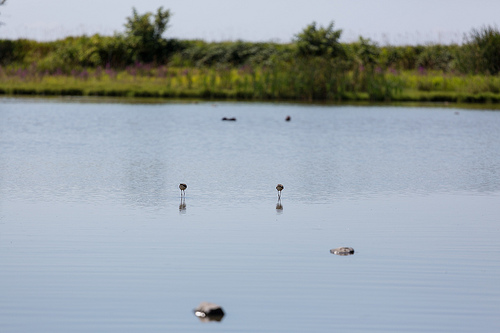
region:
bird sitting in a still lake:
[325, 242, 357, 263]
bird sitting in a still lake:
[273, 179, 286, 206]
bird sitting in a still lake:
[177, 177, 191, 204]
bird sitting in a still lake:
[283, 112, 293, 126]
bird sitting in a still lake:
[218, 112, 238, 123]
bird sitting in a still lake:
[186, 295, 226, 325]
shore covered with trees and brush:
[0, 0, 495, 99]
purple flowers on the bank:
[0, 54, 459, 86]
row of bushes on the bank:
[40, 11, 499, 71]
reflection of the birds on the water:
[174, 198, 285, 215]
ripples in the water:
[3, 97, 493, 205]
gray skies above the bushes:
[3, 3, 498, 41]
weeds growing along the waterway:
[161, 63, 402, 101]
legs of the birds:
[175, 188, 284, 195]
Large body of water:
[364, 121, 461, 202]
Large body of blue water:
[23, 117, 119, 214]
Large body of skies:
[228, 8, 280, 32]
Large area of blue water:
[23, 108, 117, 219]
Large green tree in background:
[113, 3, 179, 72]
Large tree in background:
[117, 5, 176, 70]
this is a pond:
[29, 19, 444, 299]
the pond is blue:
[78, 143, 159, 250]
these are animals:
[119, 181, 416, 295]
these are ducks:
[155, 158, 400, 280]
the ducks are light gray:
[128, 139, 340, 269]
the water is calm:
[69, 128, 399, 303]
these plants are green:
[57, 25, 350, 125]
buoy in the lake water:
[176, 175, 191, 212]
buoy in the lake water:
[265, 178, 293, 219]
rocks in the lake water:
[0, 77, 17, 105]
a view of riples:
[135, 240, 170, 265]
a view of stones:
[185, 283, 250, 330]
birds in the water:
[123, 148, 414, 320]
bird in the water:
[241, 172, 307, 233]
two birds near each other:
[143, 150, 313, 249]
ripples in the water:
[321, 132, 426, 210]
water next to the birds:
[34, 132, 164, 229]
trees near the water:
[65, 15, 373, 110]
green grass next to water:
[88, 55, 244, 106]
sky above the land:
[196, 9, 281, 37]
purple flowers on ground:
[68, 53, 198, 93]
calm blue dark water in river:
[77, 127, 110, 157]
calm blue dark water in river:
[374, 196, 401, 220]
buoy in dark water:
[168, 173, 198, 213]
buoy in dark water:
[269, 171, 296, 221]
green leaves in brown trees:
[297, 37, 325, 77]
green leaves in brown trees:
[447, 37, 482, 67]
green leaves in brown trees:
[65, 44, 111, 70]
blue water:
[423, 203, 484, 292]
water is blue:
[307, 285, 347, 320]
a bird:
[171, 181, 196, 199]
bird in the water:
[170, 176, 195, 199]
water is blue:
[94, 246, 144, 295]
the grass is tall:
[411, 71, 446, 101]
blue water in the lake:
[86, 220, 145, 266]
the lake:
[80, 248, 131, 302]